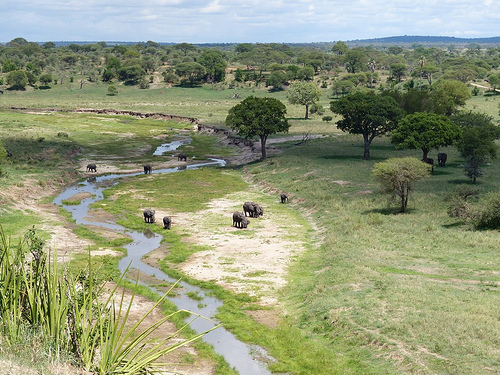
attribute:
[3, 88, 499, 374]
ground — here, grassy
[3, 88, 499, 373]
field — here, grassy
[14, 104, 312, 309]
nappier — here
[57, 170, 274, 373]
river — here, curving, small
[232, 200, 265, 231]
elephants — grouped, herd, standing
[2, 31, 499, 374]
savannah — grassy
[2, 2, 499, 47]
sky — blue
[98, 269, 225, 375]
leaves — pointy, skinny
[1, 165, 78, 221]
rim — curved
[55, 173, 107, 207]
water — reflecting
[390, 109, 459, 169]
tree — large, tall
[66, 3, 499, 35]
clouds — white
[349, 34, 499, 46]
mountain — distant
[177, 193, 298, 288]
patch — white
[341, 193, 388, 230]
grass — tall